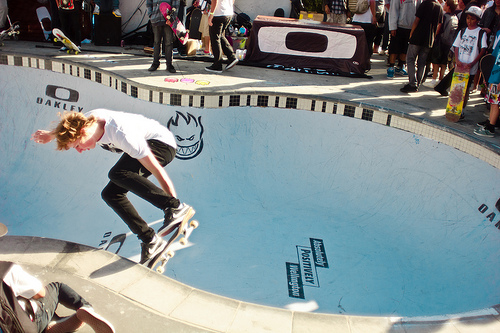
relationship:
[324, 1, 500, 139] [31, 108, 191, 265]
people watching man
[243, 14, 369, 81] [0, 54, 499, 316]
desk behind pool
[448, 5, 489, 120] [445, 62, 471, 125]
boy holding skateboard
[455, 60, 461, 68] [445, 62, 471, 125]
hand on top of skateboard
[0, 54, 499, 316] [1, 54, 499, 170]
pool has edge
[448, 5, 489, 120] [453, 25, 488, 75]
boy wearing t shirt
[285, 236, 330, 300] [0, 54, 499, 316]
writing inside pool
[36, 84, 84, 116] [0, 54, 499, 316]
logo inside pool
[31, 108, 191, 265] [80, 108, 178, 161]
man wearing shirt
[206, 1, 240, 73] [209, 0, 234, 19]
person wearing shirt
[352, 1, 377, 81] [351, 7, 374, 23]
person wearing shirt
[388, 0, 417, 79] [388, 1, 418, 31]
person wearing shirt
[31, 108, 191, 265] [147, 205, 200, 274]
man riding skateboard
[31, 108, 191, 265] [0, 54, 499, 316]
man inside pool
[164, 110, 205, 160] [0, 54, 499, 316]
fireball painted in pool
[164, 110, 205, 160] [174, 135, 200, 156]
fireball has face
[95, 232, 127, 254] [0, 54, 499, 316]
logo painted in pool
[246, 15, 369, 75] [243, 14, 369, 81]
tablecloth covering desk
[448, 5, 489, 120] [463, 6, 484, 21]
boy wearing hat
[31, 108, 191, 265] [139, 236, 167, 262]
man wearing shoe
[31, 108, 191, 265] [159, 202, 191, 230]
man wearing shoe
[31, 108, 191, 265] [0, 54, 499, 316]
man skateboarding in pool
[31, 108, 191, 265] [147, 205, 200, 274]
man on top of skateboard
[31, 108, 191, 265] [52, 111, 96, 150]
man has hair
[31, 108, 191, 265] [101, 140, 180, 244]
man wearing pants